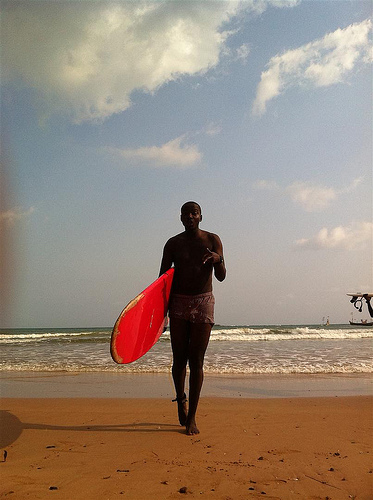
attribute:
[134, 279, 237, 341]
shorts — brown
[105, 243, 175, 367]
surfboard — red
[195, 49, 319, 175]
sky —  blue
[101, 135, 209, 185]
clouds — Thin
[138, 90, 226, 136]
sky —  blue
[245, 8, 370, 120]
clouds —  Thin